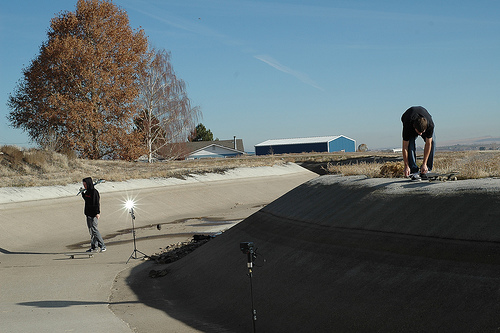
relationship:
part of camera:
[124, 208, 155, 267] [239, 242, 266, 332]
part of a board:
[74, 187, 86, 200] [75, 179, 105, 198]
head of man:
[412, 117, 427, 137] [399, 106, 435, 179]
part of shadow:
[1, 247, 29, 256] [0, 247, 90, 255]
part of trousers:
[90, 222, 95, 229] [85, 215, 105, 249]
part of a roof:
[176, 145, 185, 152] [133, 139, 244, 158]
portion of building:
[339, 139, 346, 147] [253, 135, 356, 156]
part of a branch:
[156, 85, 167, 90] [153, 78, 191, 98]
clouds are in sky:
[253, 46, 316, 92] [1, 1, 499, 152]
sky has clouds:
[1, 1, 499, 152] [253, 46, 316, 92]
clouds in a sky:
[253, 46, 316, 92] [1, 1, 499, 152]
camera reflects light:
[239, 242, 266, 332] [116, 191, 145, 218]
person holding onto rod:
[399, 106, 435, 179] [402, 173, 423, 176]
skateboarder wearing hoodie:
[76, 177, 106, 254] [80, 176, 100, 217]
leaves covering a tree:
[54, 44, 91, 99] [7, 0, 159, 162]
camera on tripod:
[239, 242, 266, 332] [125, 214, 154, 267]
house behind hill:
[134, 136, 246, 162] [0, 144, 254, 182]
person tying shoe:
[399, 106, 435, 179] [409, 173, 419, 181]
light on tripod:
[116, 191, 145, 218] [125, 214, 154, 267]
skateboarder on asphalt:
[76, 177, 106, 254] [0, 170, 319, 332]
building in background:
[253, 135, 356, 156] [0, 0, 498, 159]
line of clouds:
[122, 1, 338, 98] [253, 46, 316, 92]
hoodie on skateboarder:
[80, 176, 100, 217] [76, 177, 106, 254]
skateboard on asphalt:
[66, 250, 96, 260] [0, 170, 319, 332]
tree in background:
[7, 0, 159, 162] [0, 0, 498, 159]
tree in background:
[129, 47, 205, 163] [0, 0, 498, 159]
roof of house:
[133, 139, 244, 158] [476, 146, 485, 153]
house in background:
[134, 136, 246, 162] [0, 0, 498, 159]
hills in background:
[434, 135, 499, 178] [0, 0, 498, 159]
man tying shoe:
[399, 106, 435, 179] [409, 173, 419, 181]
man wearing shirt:
[399, 106, 435, 179] [400, 105, 434, 141]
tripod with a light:
[125, 214, 154, 267] [116, 191, 145, 218]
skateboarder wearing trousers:
[76, 177, 106, 254] [85, 215, 105, 249]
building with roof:
[253, 135, 356, 156] [254, 135, 345, 148]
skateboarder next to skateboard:
[76, 177, 106, 254] [66, 250, 96, 260]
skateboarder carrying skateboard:
[76, 177, 106, 254] [75, 179, 105, 198]